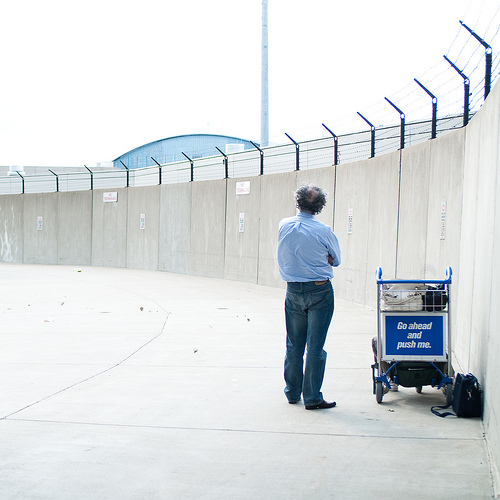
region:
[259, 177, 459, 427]
man standing beside the buggy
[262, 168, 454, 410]
man standing beside the buggy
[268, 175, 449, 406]
man standing beside the buggy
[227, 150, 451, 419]
man standing beside the buggy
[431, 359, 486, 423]
laptop bag on the floor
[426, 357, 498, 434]
laptop bag on the floor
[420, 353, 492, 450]
laptop bag on the floor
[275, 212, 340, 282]
blue cotton dress shirt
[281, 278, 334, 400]
medium blue denim jeans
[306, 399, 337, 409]
black leather dress shoes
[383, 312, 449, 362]
blue and white sign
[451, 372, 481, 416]
black fabric brief case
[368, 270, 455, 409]
metal and plastic cart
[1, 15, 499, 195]
metal and wire barrier fence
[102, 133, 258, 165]
blue metal storage building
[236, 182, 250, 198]
white sign on wall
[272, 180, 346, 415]
a person standing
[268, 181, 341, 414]
a guy in blue jeans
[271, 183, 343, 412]
back side of person standing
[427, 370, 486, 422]
a bag on ground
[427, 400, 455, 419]
strap of the bag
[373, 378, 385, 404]
wheel of the cart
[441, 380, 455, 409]
wheel of the cart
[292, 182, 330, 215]
balding head of the guy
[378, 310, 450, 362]
a sign on the cart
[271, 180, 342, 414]
a person wearing blue jeans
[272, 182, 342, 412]
person wearing blue shirt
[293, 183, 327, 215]
a balding head of the person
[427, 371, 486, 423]
a black bag on the ground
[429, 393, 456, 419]
a strap of the bag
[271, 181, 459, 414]
a person standing next to the cart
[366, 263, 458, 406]
a luggage cart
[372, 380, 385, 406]
a wheel of the cart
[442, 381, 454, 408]
a wheel of the cart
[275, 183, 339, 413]
man with balding head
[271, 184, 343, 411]
man wearing a blue shirt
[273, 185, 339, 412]
man wearing blue jeans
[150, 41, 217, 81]
a view of sky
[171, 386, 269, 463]
a view of surface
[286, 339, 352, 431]
a view of shoes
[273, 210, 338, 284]
a blue dress shirt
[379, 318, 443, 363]
a blue and white sign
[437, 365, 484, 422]
a black man's bag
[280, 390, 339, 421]
pair of black dress shoes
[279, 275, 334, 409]
dark dress pants on a man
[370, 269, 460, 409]
a blue and silver cart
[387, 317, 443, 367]
words on a sign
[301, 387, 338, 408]
a large black shoe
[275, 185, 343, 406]
man is crossing his arms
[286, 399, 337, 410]
shoes are black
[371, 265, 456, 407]
luggage cart is beside man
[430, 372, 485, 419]
bag is on the floor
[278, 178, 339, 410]
man is wearing jeans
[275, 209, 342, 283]
shirt is blue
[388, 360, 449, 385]
suit case at the bottom of cart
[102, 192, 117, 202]
sign posted on wall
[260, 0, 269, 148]
pole is beyond walls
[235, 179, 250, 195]
sign is posted on wall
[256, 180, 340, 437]
a man standing outside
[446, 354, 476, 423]
a black bag on the ground